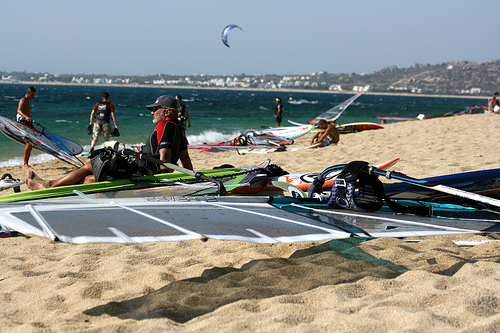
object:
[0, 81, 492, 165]
water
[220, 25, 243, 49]
kite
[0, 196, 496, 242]
surfboard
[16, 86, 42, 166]
man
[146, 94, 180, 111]
cap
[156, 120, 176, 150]
sleeve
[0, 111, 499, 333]
sand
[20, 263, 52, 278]
footprints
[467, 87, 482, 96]
houses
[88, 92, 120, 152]
man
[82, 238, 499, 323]
shadow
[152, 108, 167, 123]
beard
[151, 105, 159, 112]
sunglasses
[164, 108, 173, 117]
ear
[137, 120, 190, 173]
wetsuit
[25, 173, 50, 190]
feet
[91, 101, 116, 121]
shirt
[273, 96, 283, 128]
person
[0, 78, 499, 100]
sand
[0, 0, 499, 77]
sky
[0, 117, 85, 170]
board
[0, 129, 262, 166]
waves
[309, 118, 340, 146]
man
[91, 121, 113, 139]
shorts